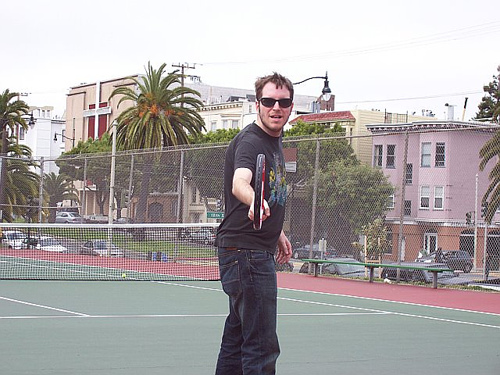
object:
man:
[213, 71, 294, 372]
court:
[0, 126, 500, 375]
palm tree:
[100, 60, 207, 240]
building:
[367, 117, 498, 272]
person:
[431, 245, 447, 265]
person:
[418, 243, 429, 258]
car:
[413, 250, 474, 274]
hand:
[247, 193, 271, 231]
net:
[0, 227, 221, 281]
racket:
[251, 154, 267, 228]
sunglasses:
[257, 96, 294, 109]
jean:
[215, 251, 281, 375]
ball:
[122, 274, 127, 279]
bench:
[304, 256, 452, 289]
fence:
[0, 127, 499, 311]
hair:
[254, 72, 294, 101]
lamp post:
[292, 70, 332, 101]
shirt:
[215, 120, 288, 254]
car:
[299, 257, 377, 280]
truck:
[381, 260, 468, 285]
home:
[62, 64, 499, 265]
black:
[234, 136, 257, 165]